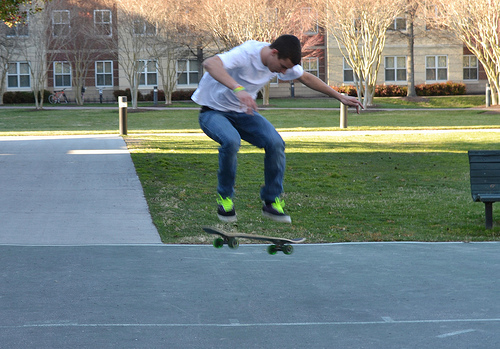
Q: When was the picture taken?
A: Daytime.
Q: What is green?
A: Grass.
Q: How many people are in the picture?
A: One.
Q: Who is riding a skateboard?
A: A guy.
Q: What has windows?
A: Buildings.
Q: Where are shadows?
A: On the grass.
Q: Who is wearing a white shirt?
A: Skateboarder.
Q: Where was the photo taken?
A: On the sidewalk.